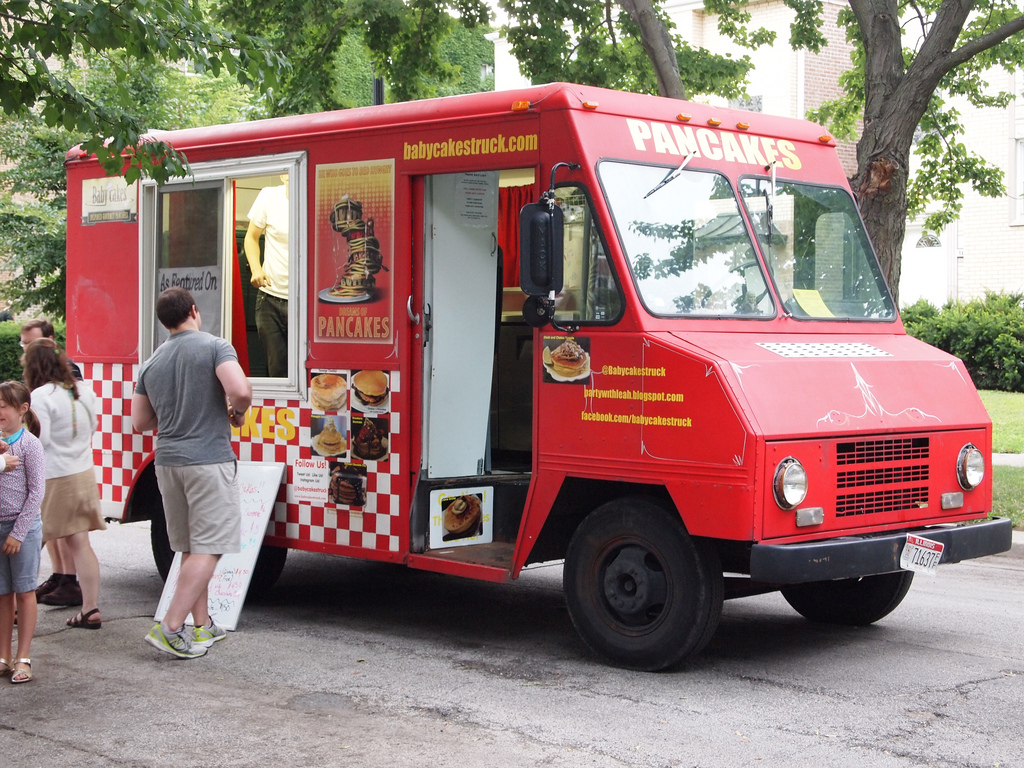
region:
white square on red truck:
[373, 510, 387, 536]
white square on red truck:
[359, 491, 375, 514]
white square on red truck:
[345, 501, 362, 530]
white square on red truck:
[305, 523, 324, 543]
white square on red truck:
[106, 395, 125, 416]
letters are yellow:
[621, 99, 822, 191]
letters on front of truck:
[623, 116, 824, 170]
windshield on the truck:
[590, 161, 895, 330]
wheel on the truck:
[563, 514, 710, 669]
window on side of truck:
[133, 183, 312, 376]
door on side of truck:
[424, 166, 538, 558]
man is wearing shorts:
[152, 463, 247, 553]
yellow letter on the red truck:
[620, 112, 646, 151]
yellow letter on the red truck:
[646, 118, 676, 158]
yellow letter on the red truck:
[669, 119, 699, 158]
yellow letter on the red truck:
[691, 119, 717, 158]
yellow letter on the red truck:
[734, 122, 764, 168]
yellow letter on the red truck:
[772, 133, 802, 171]